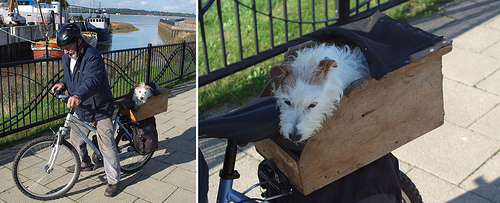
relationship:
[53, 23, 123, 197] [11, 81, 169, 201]
man riding bike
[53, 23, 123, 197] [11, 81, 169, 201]
man on bike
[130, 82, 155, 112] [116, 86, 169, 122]
dog in box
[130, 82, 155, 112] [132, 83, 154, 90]
dog has brown ears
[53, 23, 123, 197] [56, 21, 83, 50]
man wearing helmet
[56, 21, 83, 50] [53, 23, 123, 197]
helmet on man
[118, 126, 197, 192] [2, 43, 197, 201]
shadow on ground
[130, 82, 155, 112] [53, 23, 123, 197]
dog behind man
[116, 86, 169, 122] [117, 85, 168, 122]
box made of wood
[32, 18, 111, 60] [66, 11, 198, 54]
boats on ocean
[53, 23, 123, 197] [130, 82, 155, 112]
man with dog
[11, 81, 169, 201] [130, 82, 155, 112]
bike with a dog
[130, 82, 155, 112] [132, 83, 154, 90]
dog with brown ears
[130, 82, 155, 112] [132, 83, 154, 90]
dog with ears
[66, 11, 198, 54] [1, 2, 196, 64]
ocean in background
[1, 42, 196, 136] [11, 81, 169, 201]
railings along sidewalk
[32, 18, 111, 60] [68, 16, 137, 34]
boats mocked inlet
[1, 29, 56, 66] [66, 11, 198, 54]
wall along ocean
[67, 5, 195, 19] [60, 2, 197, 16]
shore in distance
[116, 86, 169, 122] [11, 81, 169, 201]
box on bike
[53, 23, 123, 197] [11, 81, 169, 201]
man riding a bike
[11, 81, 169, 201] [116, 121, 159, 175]
bike has tire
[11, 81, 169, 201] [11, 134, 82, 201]
bike has tire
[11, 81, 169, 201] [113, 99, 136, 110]
bike has seat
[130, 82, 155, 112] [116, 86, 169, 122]
dog sitting in box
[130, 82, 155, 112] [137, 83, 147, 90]
dog with a lot of hair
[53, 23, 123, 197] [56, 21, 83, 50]
man wearing a helmet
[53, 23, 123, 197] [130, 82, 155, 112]
man riding h dog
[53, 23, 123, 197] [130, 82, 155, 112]
man taking a ride with dog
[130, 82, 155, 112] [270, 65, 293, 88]
dog white and brown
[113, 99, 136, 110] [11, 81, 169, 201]
seat of bike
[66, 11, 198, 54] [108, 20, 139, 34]
ocean has land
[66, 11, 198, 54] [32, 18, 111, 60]
ocean has boats